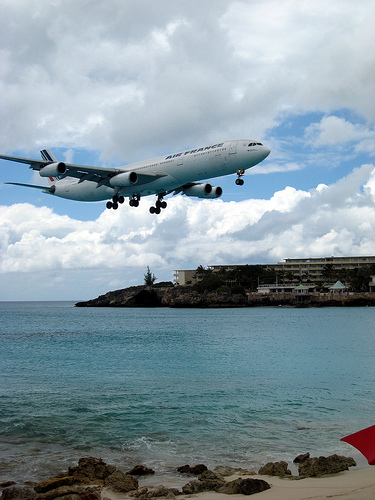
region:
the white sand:
[285, 483, 360, 496]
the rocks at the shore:
[16, 451, 344, 494]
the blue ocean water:
[53, 340, 226, 379]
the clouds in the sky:
[18, 204, 123, 269]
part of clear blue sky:
[254, 176, 273, 196]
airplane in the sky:
[1, 140, 276, 216]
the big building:
[165, 252, 373, 282]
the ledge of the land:
[73, 283, 138, 311]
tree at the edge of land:
[144, 265, 154, 286]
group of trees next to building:
[194, 261, 255, 289]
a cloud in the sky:
[5, 199, 81, 234]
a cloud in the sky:
[267, 179, 301, 211]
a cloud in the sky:
[68, 234, 136, 277]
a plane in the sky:
[12, 137, 272, 216]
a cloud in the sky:
[315, 109, 356, 152]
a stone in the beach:
[218, 474, 264, 494]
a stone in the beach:
[297, 446, 346, 482]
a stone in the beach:
[257, 454, 286, 477]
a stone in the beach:
[178, 456, 208, 474]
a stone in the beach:
[106, 469, 127, 486]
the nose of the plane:
[262, 137, 277, 160]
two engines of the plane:
[184, 181, 228, 205]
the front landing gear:
[229, 169, 252, 192]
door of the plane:
[226, 141, 241, 157]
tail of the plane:
[31, 141, 70, 184]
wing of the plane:
[0, 147, 173, 185]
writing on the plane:
[162, 136, 231, 162]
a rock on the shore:
[291, 447, 317, 467]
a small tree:
[136, 261, 162, 293]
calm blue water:
[0, 298, 373, 478]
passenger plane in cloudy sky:
[15, 60, 372, 255]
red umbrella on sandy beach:
[304, 345, 370, 495]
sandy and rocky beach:
[8, 435, 339, 495]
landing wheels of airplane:
[98, 186, 176, 211]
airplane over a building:
[3, 108, 358, 311]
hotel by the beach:
[75, 251, 369, 313]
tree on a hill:
[70, 255, 163, 312]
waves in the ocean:
[8, 317, 177, 467]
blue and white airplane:
[2, 129, 296, 221]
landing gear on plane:
[10, 128, 297, 237]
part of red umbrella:
[336, 412, 374, 467]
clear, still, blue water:
[151, 333, 214, 349]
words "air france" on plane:
[160, 141, 230, 163]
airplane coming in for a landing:
[3, 137, 275, 220]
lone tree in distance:
[142, 266, 155, 288]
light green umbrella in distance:
[290, 283, 311, 291]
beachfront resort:
[166, 250, 372, 295]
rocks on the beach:
[0, 448, 358, 497]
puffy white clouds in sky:
[169, 211, 274, 235]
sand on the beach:
[315, 481, 352, 499]